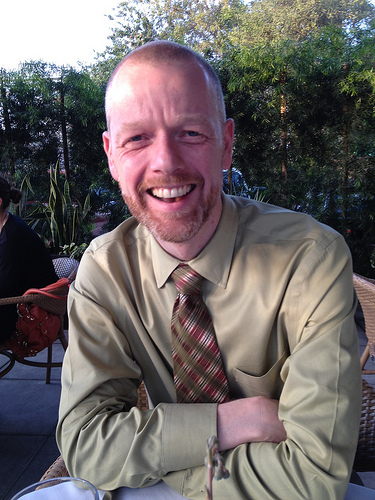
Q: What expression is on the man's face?
A: Smile.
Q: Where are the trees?
A: Behind the man.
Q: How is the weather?
A: Cool and clear.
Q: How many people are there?
A: Two.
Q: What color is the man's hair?
A: Red.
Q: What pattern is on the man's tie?
A: Plaid.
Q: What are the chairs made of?
A: Wicker.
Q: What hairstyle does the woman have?
A: Ponytail.